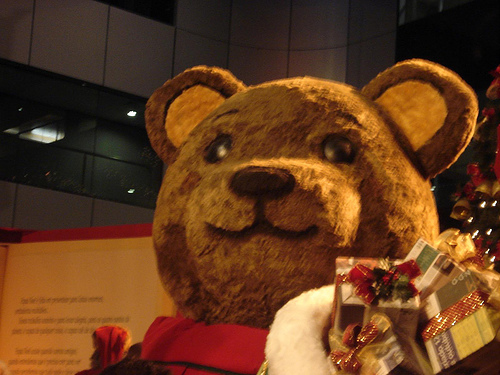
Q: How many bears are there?
A: 1.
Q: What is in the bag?
A: Gifts.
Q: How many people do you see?
A: 0.